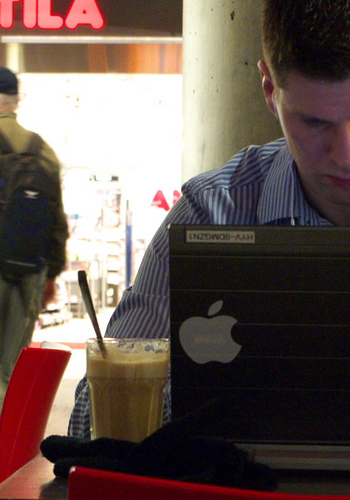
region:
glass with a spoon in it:
[68, 265, 177, 443]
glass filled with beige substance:
[82, 333, 173, 440]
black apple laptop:
[163, 219, 346, 429]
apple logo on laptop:
[174, 292, 248, 374]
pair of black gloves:
[40, 425, 277, 495]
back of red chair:
[0, 334, 63, 485]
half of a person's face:
[254, 6, 345, 211]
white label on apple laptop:
[185, 225, 263, 251]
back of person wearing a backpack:
[0, 65, 63, 332]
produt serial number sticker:
[186, 226, 256, 246]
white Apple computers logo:
[180, 297, 244, 377]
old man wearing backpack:
[1, 67, 61, 394]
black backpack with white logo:
[3, 148, 60, 292]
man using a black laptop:
[118, 2, 345, 430]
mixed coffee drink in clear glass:
[92, 331, 170, 447]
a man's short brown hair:
[269, 3, 348, 83]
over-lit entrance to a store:
[17, 70, 180, 330]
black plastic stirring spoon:
[78, 265, 117, 361]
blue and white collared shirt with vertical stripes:
[195, 142, 310, 227]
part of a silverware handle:
[77, 270, 116, 355]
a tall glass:
[88, 332, 170, 443]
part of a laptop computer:
[158, 210, 347, 463]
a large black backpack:
[2, 128, 59, 283]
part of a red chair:
[0, 335, 73, 473]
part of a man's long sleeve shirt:
[62, 121, 330, 437]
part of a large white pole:
[183, 0, 273, 182]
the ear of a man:
[257, 60, 278, 115]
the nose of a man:
[328, 121, 349, 169]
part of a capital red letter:
[63, 0, 107, 30]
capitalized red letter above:
[3, 0, 121, 29]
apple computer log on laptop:
[175, 293, 248, 367]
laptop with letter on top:
[169, 225, 340, 270]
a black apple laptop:
[170, 222, 344, 462]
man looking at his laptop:
[205, 73, 340, 432]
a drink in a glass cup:
[74, 263, 166, 443]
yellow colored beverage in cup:
[73, 269, 170, 445]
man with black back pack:
[1, 69, 70, 286]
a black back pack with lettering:
[7, 150, 68, 275]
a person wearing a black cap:
[3, 73, 51, 262]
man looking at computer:
[62, 2, 349, 458]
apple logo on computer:
[179, 297, 252, 369]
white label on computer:
[182, 226, 265, 248]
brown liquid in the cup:
[81, 335, 165, 443]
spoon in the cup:
[68, 264, 121, 355]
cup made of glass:
[75, 332, 165, 433]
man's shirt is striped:
[61, 100, 310, 435]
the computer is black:
[170, 215, 349, 471]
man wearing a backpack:
[1, 62, 62, 426]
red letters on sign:
[0, 2, 107, 40]